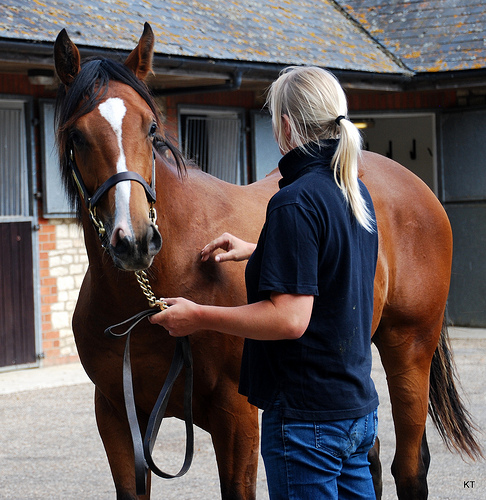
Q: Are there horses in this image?
A: Yes, there is a horse.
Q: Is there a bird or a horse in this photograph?
A: Yes, there is a horse.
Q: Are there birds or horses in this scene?
A: Yes, there is a horse.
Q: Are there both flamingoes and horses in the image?
A: No, there is a horse but no flamingoes.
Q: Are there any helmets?
A: No, there are no helmets.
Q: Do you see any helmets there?
A: No, there are no helmets.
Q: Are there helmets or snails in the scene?
A: No, there are no helmets or snails.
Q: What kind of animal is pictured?
A: The animal is a horse.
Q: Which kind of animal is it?
A: The animal is a horse.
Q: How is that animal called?
A: That is a horse.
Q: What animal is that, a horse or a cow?
A: That is a horse.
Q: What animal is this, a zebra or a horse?
A: This is a horse.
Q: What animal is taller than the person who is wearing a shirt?
A: The horse is taller than the lady.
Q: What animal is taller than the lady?
A: The horse is taller than the lady.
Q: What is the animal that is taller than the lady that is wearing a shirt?
A: The animal is a horse.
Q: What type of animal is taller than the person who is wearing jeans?
A: The animal is a horse.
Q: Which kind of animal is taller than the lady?
A: The animal is a horse.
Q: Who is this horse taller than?
A: The horse is taller than the lady.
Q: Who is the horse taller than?
A: The horse is taller than the lady.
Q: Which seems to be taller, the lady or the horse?
A: The horse is taller than the lady.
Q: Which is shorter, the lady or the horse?
A: The lady is shorter than the horse.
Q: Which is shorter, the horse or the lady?
A: The lady is shorter than the horse.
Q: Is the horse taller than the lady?
A: Yes, the horse is taller than the lady.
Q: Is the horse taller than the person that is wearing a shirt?
A: Yes, the horse is taller than the lady.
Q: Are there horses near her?
A: Yes, there is a horse near the lady.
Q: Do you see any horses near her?
A: Yes, there is a horse near the lady.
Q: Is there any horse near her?
A: Yes, there is a horse near the lady.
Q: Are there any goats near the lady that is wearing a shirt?
A: No, there is a horse near the lady.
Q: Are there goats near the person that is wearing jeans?
A: No, there is a horse near the lady.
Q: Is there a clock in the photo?
A: No, there are no clocks.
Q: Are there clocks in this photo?
A: No, there are no clocks.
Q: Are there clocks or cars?
A: No, there are no clocks or cars.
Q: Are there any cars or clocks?
A: No, there are no clocks or cars.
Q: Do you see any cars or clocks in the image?
A: No, there are no clocks or cars.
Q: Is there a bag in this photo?
A: No, there are no bags.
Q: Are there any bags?
A: No, there are no bags.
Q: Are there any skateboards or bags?
A: No, there are no bags or skateboards.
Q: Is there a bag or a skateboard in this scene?
A: No, there are no bags or skateboards.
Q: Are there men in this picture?
A: No, there are no men.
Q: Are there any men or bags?
A: No, there are no men or bags.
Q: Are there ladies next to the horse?
A: Yes, there is a lady next to the horse.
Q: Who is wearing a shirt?
A: The lady is wearing a shirt.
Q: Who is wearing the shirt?
A: The lady is wearing a shirt.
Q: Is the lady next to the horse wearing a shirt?
A: Yes, the lady is wearing a shirt.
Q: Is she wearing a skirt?
A: No, the lady is wearing a shirt.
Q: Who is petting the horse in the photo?
A: The lady is petting the horse.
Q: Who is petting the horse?
A: The lady is petting the horse.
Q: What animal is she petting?
A: The lady is petting the horse.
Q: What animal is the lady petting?
A: The lady is petting the horse.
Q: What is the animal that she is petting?
A: The animal is a horse.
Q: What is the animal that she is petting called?
A: The animal is a horse.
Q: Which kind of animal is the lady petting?
A: The lady is petting the horse.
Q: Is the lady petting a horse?
A: Yes, the lady is petting a horse.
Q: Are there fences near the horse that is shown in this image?
A: No, there is a lady near the horse.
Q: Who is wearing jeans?
A: The lady is wearing jeans.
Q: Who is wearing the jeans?
A: The lady is wearing jeans.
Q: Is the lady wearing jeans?
A: Yes, the lady is wearing jeans.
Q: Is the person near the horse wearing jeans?
A: Yes, the lady is wearing jeans.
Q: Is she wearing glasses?
A: No, the lady is wearing jeans.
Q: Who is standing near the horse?
A: The lady is standing near the horse.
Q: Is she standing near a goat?
A: No, the lady is standing near the horse.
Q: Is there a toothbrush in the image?
A: No, there are no toothbrushes.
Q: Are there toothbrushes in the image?
A: No, there are no toothbrushes.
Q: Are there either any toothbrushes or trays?
A: No, there are no toothbrushes or trays.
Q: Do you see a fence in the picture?
A: No, there are no fences.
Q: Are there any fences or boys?
A: No, there are no fences or boys.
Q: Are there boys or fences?
A: No, there are no fences or boys.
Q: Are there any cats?
A: No, there are no cats.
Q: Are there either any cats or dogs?
A: No, there are no cats or dogs.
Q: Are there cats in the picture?
A: No, there are no cats.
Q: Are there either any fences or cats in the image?
A: No, there are no cats or fences.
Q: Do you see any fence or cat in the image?
A: No, there are no cats or fences.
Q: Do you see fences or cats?
A: No, there are no cats or fences.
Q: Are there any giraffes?
A: No, there are no giraffes.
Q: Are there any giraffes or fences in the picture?
A: No, there are no giraffes or fences.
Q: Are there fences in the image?
A: No, there are no fences.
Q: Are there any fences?
A: No, there are no fences.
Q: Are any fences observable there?
A: No, there are no fences.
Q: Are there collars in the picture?
A: Yes, there is a collar.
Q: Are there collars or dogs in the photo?
A: Yes, there is a collar.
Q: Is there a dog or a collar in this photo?
A: Yes, there is a collar.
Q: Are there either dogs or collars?
A: Yes, there is a collar.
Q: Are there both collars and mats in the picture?
A: No, there is a collar but no mats.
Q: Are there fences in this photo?
A: No, there are no fences.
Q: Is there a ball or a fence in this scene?
A: No, there are no fences or balls.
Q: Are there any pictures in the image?
A: No, there are no pictures.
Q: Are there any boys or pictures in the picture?
A: No, there are no pictures or boys.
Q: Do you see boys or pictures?
A: No, there are no pictures or boys.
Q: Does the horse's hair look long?
A: Yes, the hair is long.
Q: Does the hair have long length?
A: Yes, the hair is long.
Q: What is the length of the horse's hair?
A: The hair is long.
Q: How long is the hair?
A: The hair is long.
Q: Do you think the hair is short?
A: No, the hair is long.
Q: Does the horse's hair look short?
A: No, the hair is long.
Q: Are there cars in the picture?
A: No, there are no cars.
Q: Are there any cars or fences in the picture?
A: No, there are no cars or fences.